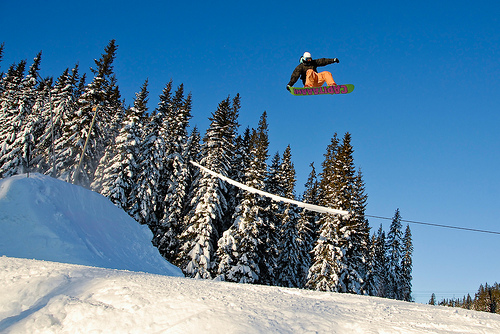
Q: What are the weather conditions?
A: It is clear.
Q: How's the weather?
A: It is clear.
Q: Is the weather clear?
A: Yes, it is clear.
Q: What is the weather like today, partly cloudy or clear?
A: It is clear.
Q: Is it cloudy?
A: No, it is clear.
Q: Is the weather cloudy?
A: No, it is clear.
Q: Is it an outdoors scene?
A: Yes, it is outdoors.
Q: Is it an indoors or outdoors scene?
A: It is outdoors.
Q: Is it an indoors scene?
A: No, it is outdoors.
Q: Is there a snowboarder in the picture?
A: Yes, there is a snowboarder.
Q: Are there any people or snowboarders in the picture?
A: Yes, there is a snowboarder.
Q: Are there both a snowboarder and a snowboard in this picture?
A: Yes, there are both a snowboarder and a snowboard.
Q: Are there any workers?
A: No, there are no workers.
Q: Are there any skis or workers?
A: No, there are no workers or skis.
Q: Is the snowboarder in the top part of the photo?
A: Yes, the snowboarder is in the top of the image.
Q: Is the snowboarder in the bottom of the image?
A: No, the snowboarder is in the top of the image.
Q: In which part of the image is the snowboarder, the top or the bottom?
A: The snowboarder is in the top of the image.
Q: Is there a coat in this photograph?
A: Yes, there is a coat.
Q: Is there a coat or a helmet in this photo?
A: Yes, there is a coat.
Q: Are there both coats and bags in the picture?
A: No, there is a coat but no bags.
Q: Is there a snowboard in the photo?
A: Yes, there is a snowboard.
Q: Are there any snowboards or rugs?
A: Yes, there is a snowboard.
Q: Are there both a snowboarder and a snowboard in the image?
A: Yes, there are both a snowboard and a snowboarder.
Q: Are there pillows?
A: No, there are no pillows.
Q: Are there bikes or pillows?
A: No, there are no pillows or bikes.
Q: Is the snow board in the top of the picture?
A: Yes, the snow board is in the top of the image.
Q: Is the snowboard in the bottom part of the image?
A: No, the snowboard is in the top of the image.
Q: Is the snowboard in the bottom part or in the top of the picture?
A: The snowboard is in the top of the image.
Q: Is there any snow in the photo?
A: Yes, there is snow.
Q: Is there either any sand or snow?
A: Yes, there is snow.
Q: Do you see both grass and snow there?
A: No, there is snow but no grass.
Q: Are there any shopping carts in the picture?
A: No, there are no shopping carts.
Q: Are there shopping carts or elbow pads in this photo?
A: No, there are no shopping carts or elbow pads.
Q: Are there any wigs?
A: No, there are no wigs.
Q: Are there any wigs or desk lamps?
A: No, there are no wigs or desk lamps.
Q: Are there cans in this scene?
A: No, there are no cans.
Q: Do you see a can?
A: No, there are no cans.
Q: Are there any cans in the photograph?
A: No, there are no cans.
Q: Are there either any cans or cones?
A: No, there are no cans or cones.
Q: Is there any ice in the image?
A: Yes, there is ice.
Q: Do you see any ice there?
A: Yes, there is ice.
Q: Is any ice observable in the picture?
A: Yes, there is ice.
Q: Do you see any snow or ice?
A: Yes, there is ice.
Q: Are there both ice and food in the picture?
A: No, there is ice but no food.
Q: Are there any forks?
A: No, there are no forks.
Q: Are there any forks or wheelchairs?
A: No, there are no forks or wheelchairs.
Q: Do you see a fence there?
A: No, there are no fences.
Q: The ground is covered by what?
A: The ground is covered by the snow.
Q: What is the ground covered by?
A: The ground is covered by the snow.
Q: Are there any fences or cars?
A: No, there are no cars or fences.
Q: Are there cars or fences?
A: No, there are no cars or fences.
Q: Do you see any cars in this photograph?
A: No, there are no cars.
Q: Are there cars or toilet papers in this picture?
A: No, there are no cars or toilet papers.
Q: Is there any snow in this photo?
A: Yes, there is snow.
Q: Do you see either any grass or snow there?
A: Yes, there is snow.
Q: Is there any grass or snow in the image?
A: Yes, there is snow.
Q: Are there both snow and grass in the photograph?
A: No, there is snow but no grass.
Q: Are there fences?
A: No, there are no fences.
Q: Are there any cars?
A: No, there are no cars.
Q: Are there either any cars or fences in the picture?
A: No, there are no cars or fences.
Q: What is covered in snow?
A: The tree is covered in snow.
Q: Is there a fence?
A: No, there are no fences.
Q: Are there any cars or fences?
A: No, there are no fences or cars.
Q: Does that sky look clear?
A: Yes, the sky is clear.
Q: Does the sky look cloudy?
A: No, the sky is clear.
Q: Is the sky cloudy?
A: No, the sky is clear.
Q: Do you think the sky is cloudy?
A: No, the sky is clear.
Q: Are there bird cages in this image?
A: No, there are no bird cages.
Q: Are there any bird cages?
A: No, there are no bird cages.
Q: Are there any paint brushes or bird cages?
A: No, there are no bird cages or paint brushes.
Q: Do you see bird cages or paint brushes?
A: No, there are no bird cages or paint brushes.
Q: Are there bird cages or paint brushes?
A: No, there are no bird cages or paint brushes.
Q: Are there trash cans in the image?
A: No, there are no trash cans.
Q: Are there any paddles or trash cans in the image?
A: No, there are no trash cans or paddles.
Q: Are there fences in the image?
A: No, there are no fences.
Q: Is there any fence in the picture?
A: No, there are no fences.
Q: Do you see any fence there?
A: No, there are no fences.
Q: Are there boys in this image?
A: No, there are no boys.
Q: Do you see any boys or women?
A: No, there are no boys or women.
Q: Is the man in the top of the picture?
A: Yes, the man is in the top of the image.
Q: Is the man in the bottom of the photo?
A: No, the man is in the top of the image.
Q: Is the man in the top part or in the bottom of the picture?
A: The man is in the top of the image.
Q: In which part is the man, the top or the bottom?
A: The man is in the top of the image.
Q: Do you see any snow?
A: Yes, there is snow.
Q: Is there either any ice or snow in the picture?
A: Yes, there is snow.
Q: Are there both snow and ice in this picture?
A: Yes, there are both snow and ice.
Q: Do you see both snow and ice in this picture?
A: Yes, there are both snow and ice.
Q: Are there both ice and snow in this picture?
A: Yes, there are both snow and ice.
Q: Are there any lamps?
A: No, there are no lamps.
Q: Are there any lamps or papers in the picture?
A: No, there are no lamps or papers.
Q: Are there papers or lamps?
A: No, there are no lamps or papers.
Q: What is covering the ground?
A: The snow is covering the ground.